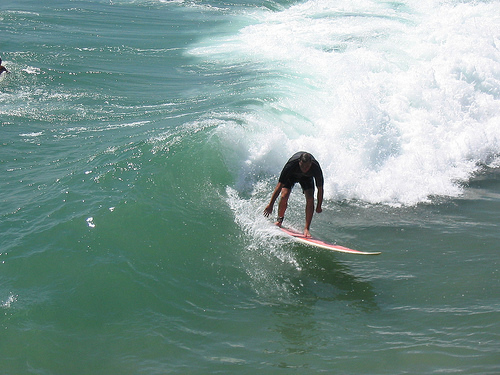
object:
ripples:
[342, 306, 410, 356]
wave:
[169, 111, 264, 186]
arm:
[317, 166, 324, 212]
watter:
[5, 6, 275, 366]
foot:
[275, 221, 282, 227]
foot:
[304, 227, 312, 238]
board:
[272, 220, 382, 255]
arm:
[266, 181, 283, 210]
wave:
[176, 1, 493, 200]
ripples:
[192, 295, 235, 318]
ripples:
[168, 324, 286, 374]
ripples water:
[64, 135, 157, 211]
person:
[0, 59, 7, 76]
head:
[296, 152, 312, 172]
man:
[261, 151, 326, 239]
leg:
[301, 185, 317, 229]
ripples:
[157, 92, 231, 140]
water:
[2, 3, 499, 374]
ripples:
[336, 262, 424, 292]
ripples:
[367, 296, 497, 368]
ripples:
[4, 120, 195, 311]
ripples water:
[146, 97, 215, 184]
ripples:
[15, 30, 111, 109]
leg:
[275, 190, 288, 220]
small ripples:
[201, 306, 346, 366]